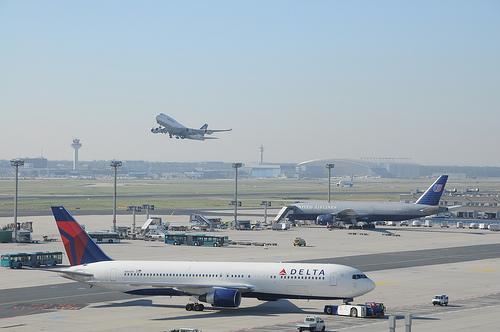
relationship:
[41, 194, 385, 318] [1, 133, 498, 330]
airplane parked at airport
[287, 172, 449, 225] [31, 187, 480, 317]
airplane parked at airport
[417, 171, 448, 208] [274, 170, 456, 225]
tail of airplane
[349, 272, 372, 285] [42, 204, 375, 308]
cockpit of airplane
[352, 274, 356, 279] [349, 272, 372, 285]
window on cockpit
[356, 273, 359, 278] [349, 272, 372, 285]
window on cockpit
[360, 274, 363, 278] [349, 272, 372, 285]
window on cockpit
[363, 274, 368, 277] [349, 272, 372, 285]
window on cockpit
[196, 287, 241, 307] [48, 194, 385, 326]
engine of airplane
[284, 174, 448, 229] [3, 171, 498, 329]
airplane sitting at airport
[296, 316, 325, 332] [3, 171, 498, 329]
vehicle used at airport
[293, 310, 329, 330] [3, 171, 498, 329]
vehicle used at airport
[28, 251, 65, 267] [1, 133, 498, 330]
vehicle used at airport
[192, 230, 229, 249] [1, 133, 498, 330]
vehicle used at airport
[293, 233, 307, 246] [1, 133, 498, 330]
vehicle used at airport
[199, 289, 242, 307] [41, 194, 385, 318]
engine of airplane